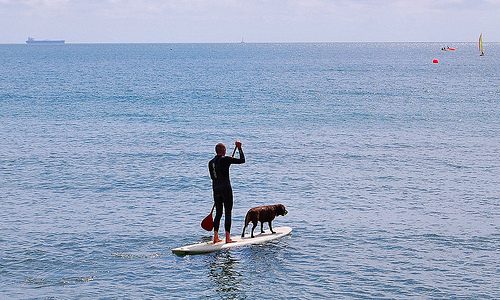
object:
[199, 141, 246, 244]
man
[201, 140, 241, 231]
paddle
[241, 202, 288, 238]
dog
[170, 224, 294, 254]
board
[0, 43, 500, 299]
water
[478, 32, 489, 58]
boat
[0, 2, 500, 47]
sky